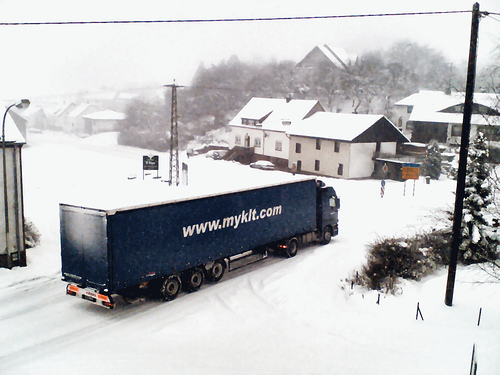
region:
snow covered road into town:
[27, 104, 484, 354]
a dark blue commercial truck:
[46, 162, 371, 312]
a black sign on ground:
[126, 143, 174, 188]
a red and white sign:
[374, 155, 403, 188]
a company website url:
[174, 198, 300, 243]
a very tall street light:
[1, 92, 53, 283]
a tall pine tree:
[446, 122, 498, 277]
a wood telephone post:
[154, 81, 196, 191]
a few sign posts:
[369, 286, 493, 332]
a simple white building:
[277, 99, 415, 189]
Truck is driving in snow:
[40, 145, 361, 323]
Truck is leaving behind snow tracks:
[16, 290, 181, 360]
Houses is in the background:
[225, 90, 401, 185]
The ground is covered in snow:
[37, 130, 107, 185]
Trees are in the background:
[131, 75, 216, 145]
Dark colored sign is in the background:
[130, 145, 160, 185]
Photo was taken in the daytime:
[25, 92, 496, 367]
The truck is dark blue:
[40, 148, 358, 326]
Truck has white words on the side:
[170, 198, 292, 245]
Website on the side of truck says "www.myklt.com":
[167, 197, 294, 248]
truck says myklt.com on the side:
[160, 196, 309, 240]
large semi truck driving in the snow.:
[22, 83, 402, 341]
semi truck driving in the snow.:
[0, 69, 426, 356]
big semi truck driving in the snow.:
[20, 51, 432, 353]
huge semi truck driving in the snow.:
[11, 56, 406, 351]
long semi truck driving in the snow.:
[25, 43, 449, 353]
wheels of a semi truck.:
[137, 257, 247, 309]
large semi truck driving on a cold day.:
[26, 83, 441, 347]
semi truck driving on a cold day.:
[12, 76, 439, 361]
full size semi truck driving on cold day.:
[24, 59, 457, 359]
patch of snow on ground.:
[13, 304, 428, 367]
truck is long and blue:
[45, 162, 357, 289]